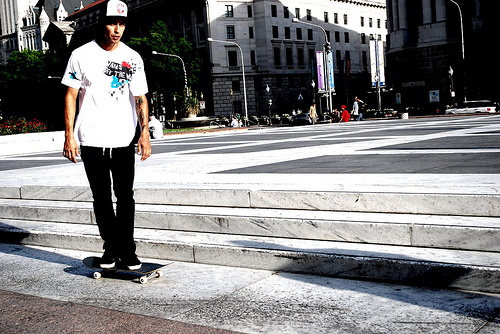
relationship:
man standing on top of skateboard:
[60, 0, 152, 266] [80, 254, 170, 284]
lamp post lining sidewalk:
[46, 74, 63, 81] [0, 241, 499, 333]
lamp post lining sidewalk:
[149, 49, 189, 90] [0, 241, 499, 333]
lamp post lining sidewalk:
[206, 37, 248, 120] [0, 241, 499, 333]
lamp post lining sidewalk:
[291, 16, 334, 111] [0, 241, 499, 333]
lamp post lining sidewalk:
[445, 0, 467, 59] [0, 241, 499, 333]